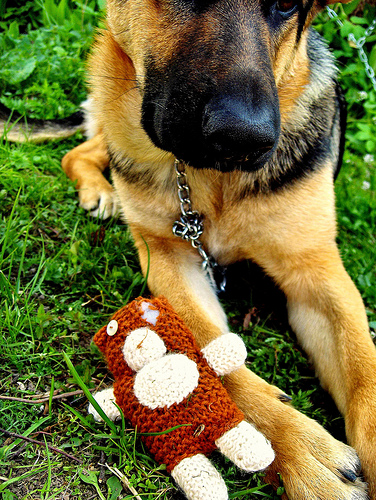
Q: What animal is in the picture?
A: Dog.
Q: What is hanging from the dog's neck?
A: A chain.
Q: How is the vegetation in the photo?
A: Healthy.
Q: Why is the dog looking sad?
A: Just woke up.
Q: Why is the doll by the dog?
A: The dog's playing with it.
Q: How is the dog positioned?
A: Laying down.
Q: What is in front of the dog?
A: Stuffed toy.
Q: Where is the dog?
A: In grass.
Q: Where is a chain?
A: On dog.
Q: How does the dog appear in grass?
A: Relaxed.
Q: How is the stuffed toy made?
A: Knitted.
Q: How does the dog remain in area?
A: Chain.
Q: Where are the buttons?
A: Toy eyes.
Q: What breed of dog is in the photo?
A: German shepherd.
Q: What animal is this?
A: Dog.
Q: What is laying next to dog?
A: Stuffed animal.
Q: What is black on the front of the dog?
A: Nose.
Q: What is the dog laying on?
A: Grass.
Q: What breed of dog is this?
A: German Shepherd Dog.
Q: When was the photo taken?
A: Daytime.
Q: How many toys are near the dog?
A: 1.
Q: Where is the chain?
A: Around the dog.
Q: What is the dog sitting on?
A: Grass.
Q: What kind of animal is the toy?
A: Bear.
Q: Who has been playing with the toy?
A: Dog.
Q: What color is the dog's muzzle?
A: Black.